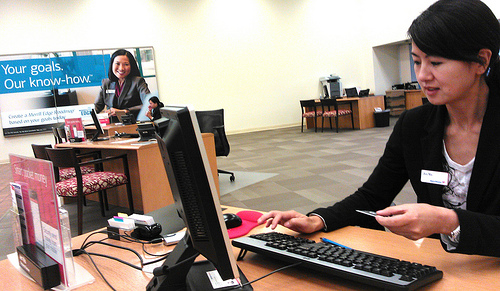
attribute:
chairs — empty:
[295, 96, 355, 127]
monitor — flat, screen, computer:
[145, 104, 255, 289]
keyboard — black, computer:
[233, 231, 444, 288]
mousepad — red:
[216, 192, 282, 256]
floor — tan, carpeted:
[231, 131, 370, 179]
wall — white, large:
[3, 4, 359, 134]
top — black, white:
[424, 129, 486, 251]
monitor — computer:
[111, 96, 252, 238]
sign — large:
[0, 54, 116, 96]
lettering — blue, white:
[3, 71, 88, 88]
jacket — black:
[368, 116, 488, 206]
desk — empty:
[290, 66, 375, 133]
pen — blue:
[319, 235, 351, 249]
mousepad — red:
[223, 205, 271, 243]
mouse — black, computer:
[221, 207, 243, 232]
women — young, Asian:
[88, 0, 496, 125]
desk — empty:
[277, 77, 391, 133]